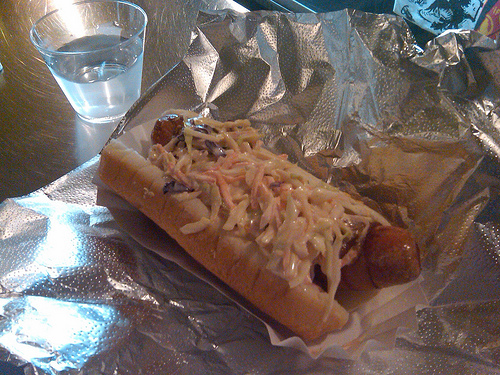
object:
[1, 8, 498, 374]
foil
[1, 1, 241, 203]
table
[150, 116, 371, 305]
cabbage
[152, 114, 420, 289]
hot dog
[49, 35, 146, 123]
water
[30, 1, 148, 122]
cup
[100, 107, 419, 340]
bun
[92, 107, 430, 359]
paper holder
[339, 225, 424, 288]
hot dog end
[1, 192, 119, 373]
reflection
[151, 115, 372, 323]
cole slaw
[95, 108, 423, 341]
food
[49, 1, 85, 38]
light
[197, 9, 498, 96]
edge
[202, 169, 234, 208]
carrot